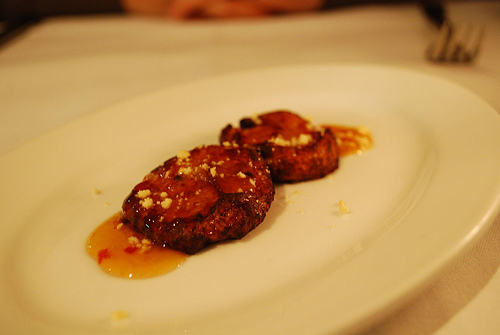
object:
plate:
[1, 63, 499, 334]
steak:
[218, 109, 339, 185]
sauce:
[84, 210, 191, 280]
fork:
[419, 0, 484, 66]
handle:
[417, 0, 445, 22]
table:
[1, 0, 500, 335]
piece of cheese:
[339, 200, 349, 213]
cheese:
[334, 127, 371, 157]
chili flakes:
[121, 143, 271, 253]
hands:
[204, 0, 261, 17]